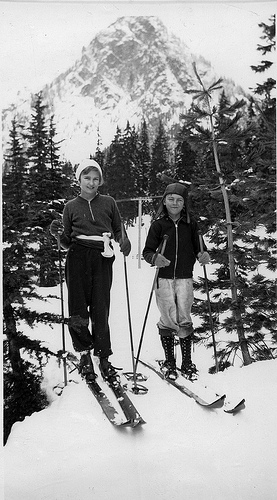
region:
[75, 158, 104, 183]
white cap on a woman's head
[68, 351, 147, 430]
a pair of skis attached to a young woman's feet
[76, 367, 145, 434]
two skis on the snow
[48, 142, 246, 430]
young woman and young man on skis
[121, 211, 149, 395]
a ski pole in the young woman's hand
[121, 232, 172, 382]
ski in the young man's hand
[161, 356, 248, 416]
skis on the young man's feet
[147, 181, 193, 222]
dark colored cap on the young man's head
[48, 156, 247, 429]
two young skiers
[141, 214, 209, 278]
black coat on a young man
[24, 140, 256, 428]
two kids on skis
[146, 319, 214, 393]
Long black boots on legs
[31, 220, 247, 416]
ski poles used by kids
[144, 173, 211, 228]
a black hat on head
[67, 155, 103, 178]
a white hat on head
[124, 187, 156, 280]
pole to ski lift seen between kids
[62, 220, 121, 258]
white tie around waist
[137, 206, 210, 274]
a zipped up black jacket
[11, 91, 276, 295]
several tall evergreen trees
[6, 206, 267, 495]
snow all over the ground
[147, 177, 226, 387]
A child posing for a picture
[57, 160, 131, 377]
A child posing for a picture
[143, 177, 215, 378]
A child skiing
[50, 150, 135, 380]
A child skiing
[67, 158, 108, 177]
A white hat for winter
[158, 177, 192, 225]
A child wearing a brown hat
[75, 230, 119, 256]
A white belt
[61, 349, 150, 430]
A pair of dark skis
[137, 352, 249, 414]
A pair of skis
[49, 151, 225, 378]
A group of kids skiing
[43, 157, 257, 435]
two skiers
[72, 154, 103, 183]
skier wearing a white hat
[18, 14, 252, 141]
tall, snow covered mountain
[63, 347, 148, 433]
skier with black skis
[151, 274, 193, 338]
skier with white pants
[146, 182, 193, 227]
skier wearing a black hat with ear flaps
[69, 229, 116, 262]
skier with a white scarf around their waist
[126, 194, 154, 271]
utility pole in the snow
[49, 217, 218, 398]
four ski poles in the snow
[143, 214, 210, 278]
black jacket with a full zipper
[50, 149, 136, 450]
Young boy is on skiis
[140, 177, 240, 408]
A small boy is on skiis.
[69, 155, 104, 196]
Young boy is wearing a white hat.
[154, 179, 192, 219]
A boy is wearing a black cap.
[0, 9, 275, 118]
A mountain top is in the distance.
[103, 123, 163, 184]
Trees are behind two boys.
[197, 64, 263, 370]
Tree is lacking some needles.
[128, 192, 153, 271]
A powerline is in the background.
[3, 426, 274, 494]
There is snow on the ground.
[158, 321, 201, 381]
The boy is wearing boots.